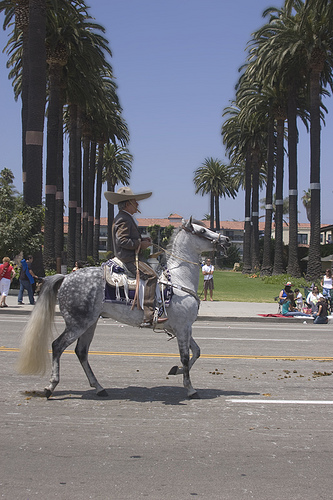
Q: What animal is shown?
A: Horse.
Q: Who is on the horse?
A: A man.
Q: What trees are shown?
A: Palm trees.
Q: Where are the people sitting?
A: Sidewalk.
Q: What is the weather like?
A: Sunny.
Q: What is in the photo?
A: A horse.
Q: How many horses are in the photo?
A: One.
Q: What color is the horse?
A: White.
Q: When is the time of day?
A: Daytime.